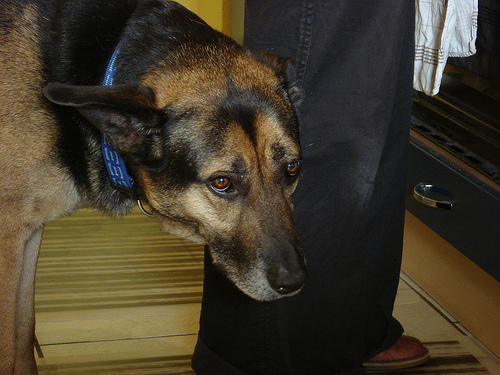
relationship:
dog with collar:
[18, 43, 288, 323] [87, 18, 147, 164]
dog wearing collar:
[0, 0, 312, 373] [88, 44, 136, 223]